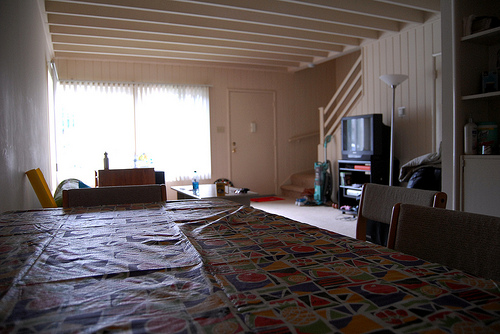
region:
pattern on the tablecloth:
[310, 295, 330, 306]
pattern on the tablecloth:
[232, 296, 255, 310]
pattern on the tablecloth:
[158, 298, 179, 306]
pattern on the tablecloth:
[234, 273, 266, 293]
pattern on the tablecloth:
[319, 273, 346, 291]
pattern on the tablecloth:
[86, 295, 105, 310]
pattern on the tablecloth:
[266, 252, 283, 269]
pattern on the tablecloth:
[277, 293, 307, 317]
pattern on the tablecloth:
[281, 229, 316, 251]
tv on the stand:
[331, 105, 381, 157]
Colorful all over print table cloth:
[0, 195, 499, 331]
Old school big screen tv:
[338, 113, 395, 158]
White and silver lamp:
[373, 68, 409, 184]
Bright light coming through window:
[55, 80, 210, 177]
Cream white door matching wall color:
[228, 88, 278, 191]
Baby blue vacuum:
[310, 136, 332, 203]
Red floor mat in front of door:
[251, 190, 283, 206]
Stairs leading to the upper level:
[280, 52, 363, 192]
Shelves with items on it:
[453, 5, 499, 153]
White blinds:
[58, 83, 213, 178]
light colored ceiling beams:
[41, 0, 437, 60]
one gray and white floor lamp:
[375, 68, 409, 184]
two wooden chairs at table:
[355, 178, 499, 292]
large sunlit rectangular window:
[52, 74, 217, 191]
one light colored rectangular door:
[222, 80, 282, 197]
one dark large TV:
[336, 110, 392, 162]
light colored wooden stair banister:
[309, 47, 370, 164]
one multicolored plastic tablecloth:
[0, 198, 499, 333]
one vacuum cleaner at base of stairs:
[283, 133, 338, 210]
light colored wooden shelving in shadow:
[444, 1, 499, 210]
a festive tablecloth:
[2, 198, 498, 333]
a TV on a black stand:
[339, 113, 387, 160]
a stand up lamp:
[384, 73, 410, 186]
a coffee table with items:
[179, 178, 251, 198]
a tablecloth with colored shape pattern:
[1, 200, 494, 332]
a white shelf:
[446, 3, 499, 161]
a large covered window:
[51, 75, 208, 174]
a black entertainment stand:
[334, 157, 390, 214]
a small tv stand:
[334, 157, 387, 207]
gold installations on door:
[229, 138, 237, 152]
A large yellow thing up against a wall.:
[24, 168, 56, 209]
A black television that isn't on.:
[338, 110, 390, 161]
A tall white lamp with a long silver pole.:
[378, 71, 409, 183]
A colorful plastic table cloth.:
[3, 201, 499, 332]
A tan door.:
[223, 87, 280, 197]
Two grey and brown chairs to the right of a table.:
[355, 180, 499, 284]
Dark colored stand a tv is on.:
[335, 157, 400, 209]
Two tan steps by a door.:
[278, 173, 317, 198]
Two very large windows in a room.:
[58, 79, 211, 184]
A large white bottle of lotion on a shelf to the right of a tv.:
[462, 116, 479, 156]